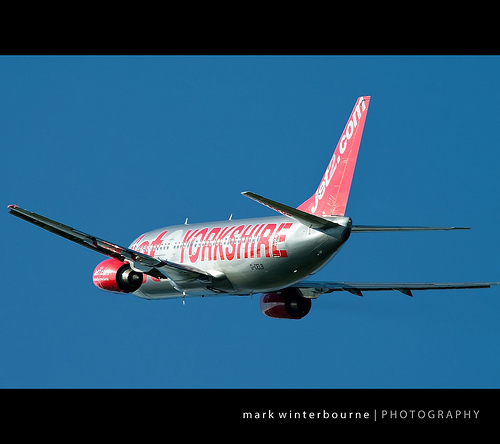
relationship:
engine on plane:
[255, 287, 324, 325] [61, 85, 468, 332]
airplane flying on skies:
[6, 80, 497, 322] [1, 54, 481, 389]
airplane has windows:
[6, 80, 497, 322] [142, 235, 257, 248]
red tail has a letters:
[280, 85, 391, 235] [308, 100, 376, 218]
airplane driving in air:
[6, 80, 497, 322] [0, 43, 500, 397]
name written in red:
[174, 221, 293, 259] [182, 233, 280, 245]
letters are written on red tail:
[308, 100, 376, 218] [280, 85, 391, 235]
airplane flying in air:
[6, 80, 497, 322] [0, 43, 500, 397]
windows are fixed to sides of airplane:
[125, 240, 275, 252] [6, 80, 497, 322]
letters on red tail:
[308, 100, 376, 218] [280, 85, 391, 235]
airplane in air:
[6, 80, 497, 322] [0, 43, 500, 397]